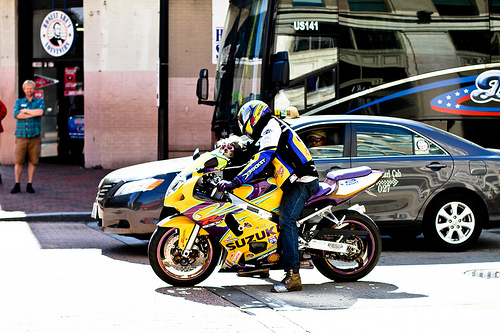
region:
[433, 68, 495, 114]
Red, white, and blue design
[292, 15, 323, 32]
Bus number US141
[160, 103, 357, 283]
Man riding a bicycle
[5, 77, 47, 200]
Man standing on sidewalk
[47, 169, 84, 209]
Sidewalk made of red bricks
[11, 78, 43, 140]
Man wearing blue checked shirt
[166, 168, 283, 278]
Yellow motorcycle with Suzuki brand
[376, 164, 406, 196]
Cab logo on side of car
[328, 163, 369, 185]
Purple passenger seat on bicycle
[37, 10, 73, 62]
Abraham Lincoln on round sign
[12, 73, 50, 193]
A man standing ousude a shop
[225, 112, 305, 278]
A man on a protective gear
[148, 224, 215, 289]
A black bike wheel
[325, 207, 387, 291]
A black bike wheel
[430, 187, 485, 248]
A black car wheel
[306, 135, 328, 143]
A black pair of sun glasses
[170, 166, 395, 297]
A suzuki motor bike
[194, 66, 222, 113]
A bus's side mirror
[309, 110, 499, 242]
A shinny grey car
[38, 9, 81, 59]
A man's drawing on a door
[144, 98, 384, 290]
Man riding a motorbike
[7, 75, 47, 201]
Man standing on the sidewalk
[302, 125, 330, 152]
Person is wearing a hat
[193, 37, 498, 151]
A big black bus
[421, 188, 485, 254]
A black round tire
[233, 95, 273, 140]
Helmet on rider's head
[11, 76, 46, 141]
Man has his arms crossed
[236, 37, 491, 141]
Reflections on the bus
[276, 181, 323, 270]
A pair of blue jeans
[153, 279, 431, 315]
Motorbike's shadow on the road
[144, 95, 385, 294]
A person riding a Suzuki motorcycle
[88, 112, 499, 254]
A black four-door taxi cab sedan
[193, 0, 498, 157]
A black bus on a road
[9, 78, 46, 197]
Man standing on a sidewalk with arms crossed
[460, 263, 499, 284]
Manhole cover on a road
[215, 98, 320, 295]
Person wearing helmet and motorcycle riding gear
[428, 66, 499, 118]
Red, white and blue logo on side of a bus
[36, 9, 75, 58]
White circle logo with Abraham Lincoln's picture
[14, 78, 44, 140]
Man wearing a blue plaid shirt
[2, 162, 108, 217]
Cobblestone sidewalk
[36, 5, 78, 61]
Round sign on window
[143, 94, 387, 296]
Person on a motorcycle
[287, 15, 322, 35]
"US141" written on a bus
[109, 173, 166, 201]
Headlight on a car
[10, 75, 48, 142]
Man wearing a green shirt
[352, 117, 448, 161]
A window on side of the car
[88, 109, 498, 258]
A blue car on the road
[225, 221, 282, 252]
The word "SUZUKI" on side of motorbike